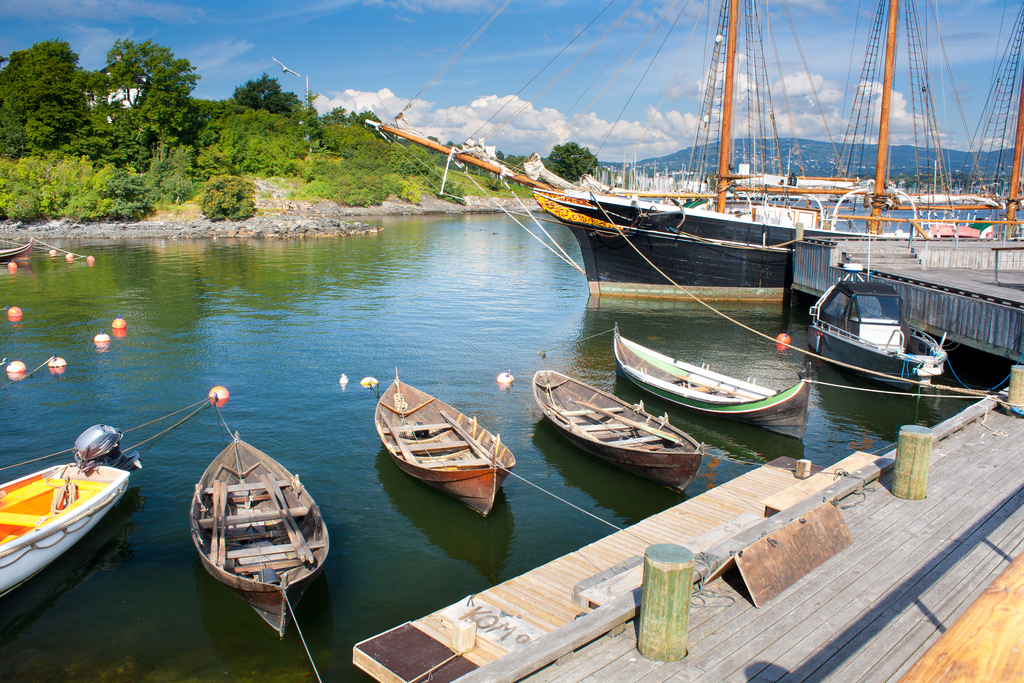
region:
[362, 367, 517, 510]
boat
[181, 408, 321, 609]
boat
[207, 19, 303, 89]
white clouds in the blue sky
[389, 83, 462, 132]
white clouds in the blue sky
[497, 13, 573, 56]
white clouds in the blue sky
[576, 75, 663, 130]
white clouds in the blue sky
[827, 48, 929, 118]
white clouds in the blue sky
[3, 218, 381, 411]
Multiple orange and white floating balls.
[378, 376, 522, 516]
A red and brown canoe.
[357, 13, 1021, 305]
A ship at the dock.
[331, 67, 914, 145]
Fluffy white clouds.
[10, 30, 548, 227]
Bushes and trees on a hill.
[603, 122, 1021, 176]
Mountain range in the distance.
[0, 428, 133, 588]
A yellow,orange,and white motor boat.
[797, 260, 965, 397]
A small blue and white boat.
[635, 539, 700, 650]
A short wooden post.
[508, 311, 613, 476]
A person eating a orange.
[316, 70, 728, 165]
clouds in the sky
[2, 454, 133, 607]
a small yellow boat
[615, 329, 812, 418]
a small green boat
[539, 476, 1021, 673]
the boat dock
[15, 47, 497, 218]
trees behind the water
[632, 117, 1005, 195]
a mountain behind the boats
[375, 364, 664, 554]
a boat tied to the dock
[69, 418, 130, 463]
a motor on the boat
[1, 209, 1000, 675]
Water covering the surface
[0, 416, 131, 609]
Yellow coloring inside the boat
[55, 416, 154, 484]
motor on the boat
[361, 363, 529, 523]
boat in the water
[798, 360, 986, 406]
rope tying boat to the dock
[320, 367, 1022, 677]
Dock in the water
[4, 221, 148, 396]
bouys in the water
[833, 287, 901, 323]
window on the boat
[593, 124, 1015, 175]
Land in the distance